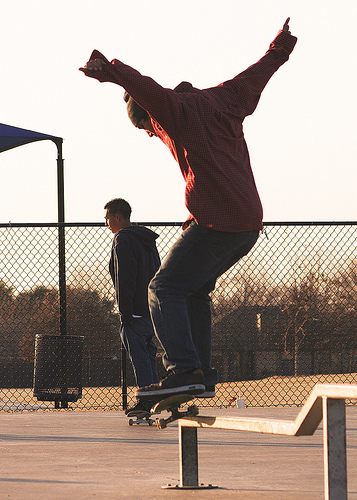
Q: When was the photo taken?
A: Daytime.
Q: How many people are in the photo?
A: Two.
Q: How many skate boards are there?
A: Two.